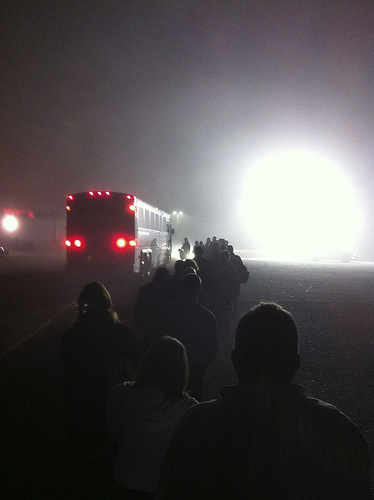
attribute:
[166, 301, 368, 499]
person — walking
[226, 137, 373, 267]
light — large, bright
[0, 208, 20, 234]
light — small, illuminating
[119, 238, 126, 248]
light — red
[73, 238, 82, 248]
light — red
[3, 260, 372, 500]
ground — dark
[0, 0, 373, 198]
sky — black